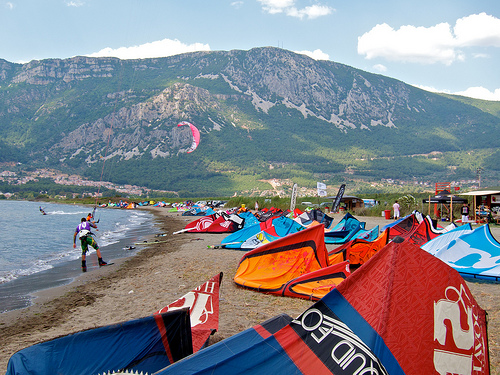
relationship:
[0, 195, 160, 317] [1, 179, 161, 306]
ocean in ocean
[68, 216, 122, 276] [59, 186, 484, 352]
man on beach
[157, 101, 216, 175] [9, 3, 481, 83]
kite in sky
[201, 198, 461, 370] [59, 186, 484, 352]
kites on beach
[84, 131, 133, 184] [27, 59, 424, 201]
tree in distance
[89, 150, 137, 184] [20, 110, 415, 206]
tree in distance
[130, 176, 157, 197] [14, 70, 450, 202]
tree in distance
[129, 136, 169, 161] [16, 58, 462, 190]
tree in distance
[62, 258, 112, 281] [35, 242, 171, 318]
footstep on sand